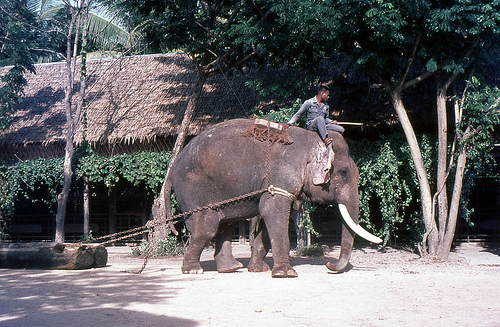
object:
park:
[0, 0, 500, 326]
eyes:
[337, 166, 351, 180]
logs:
[0, 241, 114, 269]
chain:
[63, 181, 297, 246]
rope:
[75, 184, 275, 248]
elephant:
[160, 117, 384, 279]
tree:
[434, 0, 492, 261]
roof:
[0, 53, 303, 142]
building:
[0, 52, 336, 239]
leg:
[256, 180, 296, 270]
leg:
[175, 200, 219, 264]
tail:
[163, 157, 187, 236]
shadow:
[1, 267, 199, 326]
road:
[1, 248, 499, 326]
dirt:
[352, 247, 412, 272]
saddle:
[245, 115, 298, 145]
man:
[288, 82, 349, 148]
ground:
[0, 241, 500, 326]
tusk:
[327, 203, 388, 248]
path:
[450, 238, 500, 270]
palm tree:
[36, 0, 102, 248]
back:
[176, 116, 320, 155]